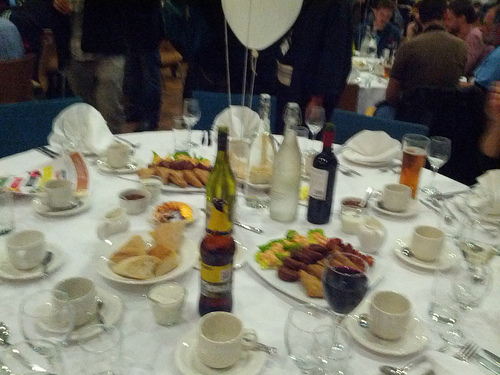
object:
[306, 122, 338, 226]
bottle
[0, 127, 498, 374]
table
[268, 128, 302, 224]
clear bottle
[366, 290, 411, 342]
cup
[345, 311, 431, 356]
small plate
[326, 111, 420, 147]
chair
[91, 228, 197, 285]
dish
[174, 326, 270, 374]
plate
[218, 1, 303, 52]
balloon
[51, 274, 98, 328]
cup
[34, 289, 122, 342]
plate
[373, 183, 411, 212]
cup and saucer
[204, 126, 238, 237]
bottle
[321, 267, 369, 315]
red wine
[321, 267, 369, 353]
glass of red wine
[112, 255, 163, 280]
bread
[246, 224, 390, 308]
dishes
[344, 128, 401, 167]
napkin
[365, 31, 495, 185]
people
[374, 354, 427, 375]
silverware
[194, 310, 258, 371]
teacup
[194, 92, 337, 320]
wine bottles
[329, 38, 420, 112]
table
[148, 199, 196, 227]
bowl of chips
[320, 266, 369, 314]
drink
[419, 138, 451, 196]
wine glass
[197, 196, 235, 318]
beer bottle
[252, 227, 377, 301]
plate of food